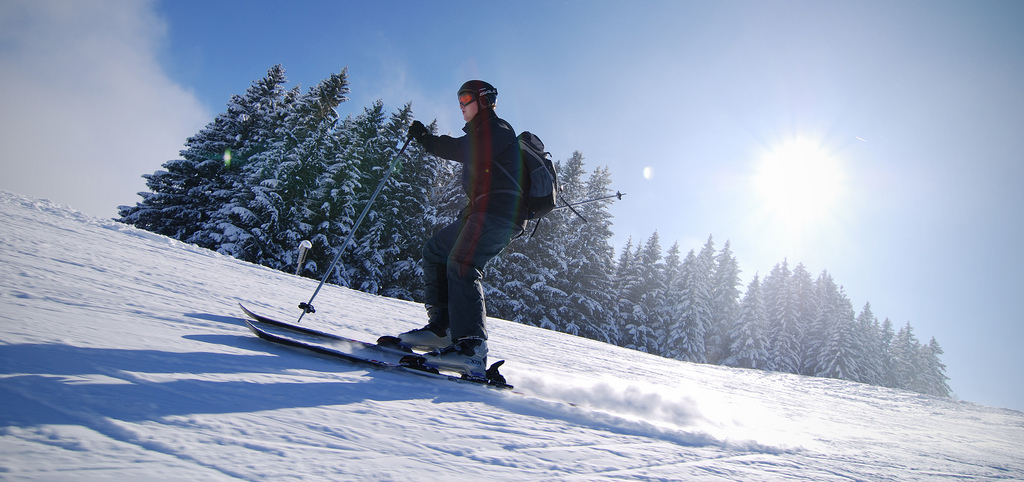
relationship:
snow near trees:
[9, 200, 1018, 479] [156, 34, 953, 383]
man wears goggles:
[247, 67, 625, 414] [456, 92, 479, 109]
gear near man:
[427, 131, 561, 326] [247, 67, 625, 414]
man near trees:
[247, 67, 625, 414] [156, 34, 953, 383]